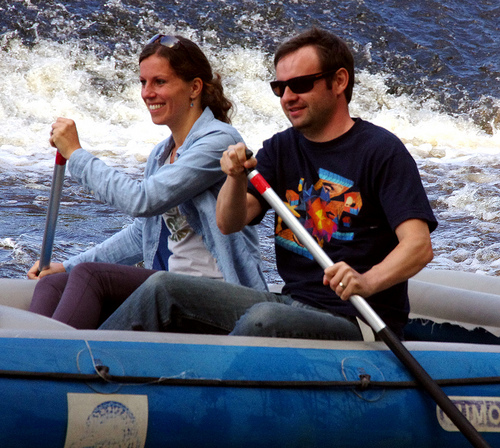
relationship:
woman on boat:
[105, 17, 221, 139] [14, 288, 419, 430]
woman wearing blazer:
[105, 17, 221, 139] [82, 117, 244, 289]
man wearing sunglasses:
[256, 23, 362, 157] [261, 73, 331, 98]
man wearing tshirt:
[256, 23, 362, 157] [229, 132, 425, 331]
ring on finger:
[337, 277, 347, 290] [330, 277, 356, 300]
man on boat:
[256, 23, 362, 157] [14, 288, 419, 430]